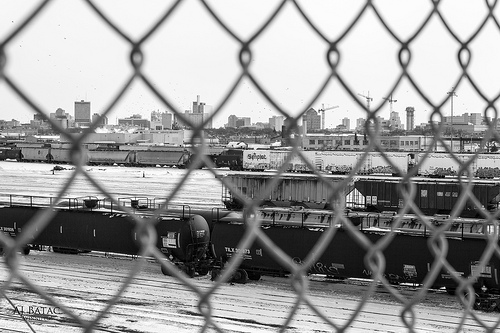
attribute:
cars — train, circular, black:
[17, 161, 497, 301]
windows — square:
[301, 127, 376, 153]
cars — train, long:
[7, 126, 257, 185]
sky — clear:
[4, 3, 498, 123]